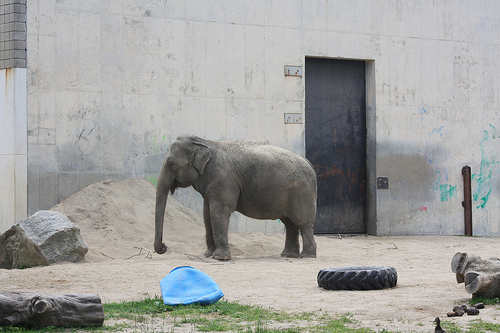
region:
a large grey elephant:
[141, 129, 329, 264]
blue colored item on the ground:
[156, 261, 226, 306]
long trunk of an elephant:
[150, 179, 173, 258]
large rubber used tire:
[312, 263, 402, 294]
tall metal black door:
[296, 50, 381, 237]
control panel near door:
[375, 173, 392, 193]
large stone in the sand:
[0, 205, 92, 270]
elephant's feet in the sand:
[199, 240, 321, 265]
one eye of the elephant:
[167, 157, 177, 170]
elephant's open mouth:
[165, 180, 180, 199]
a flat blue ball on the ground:
[144, 262, 255, 326]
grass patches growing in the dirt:
[233, 304, 262, 329]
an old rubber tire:
[323, 262, 414, 299]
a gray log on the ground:
[0, 282, 117, 331]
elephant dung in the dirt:
[446, 295, 494, 315]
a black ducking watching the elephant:
[434, 317, 447, 332]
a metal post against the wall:
[459, 162, 479, 237]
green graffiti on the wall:
[480, 142, 492, 230]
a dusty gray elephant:
[131, 137, 337, 256]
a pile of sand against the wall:
[89, 181, 148, 261]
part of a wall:
[404, 86, 451, 141]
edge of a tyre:
[341, 271, 371, 293]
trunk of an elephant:
[147, 210, 175, 239]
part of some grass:
[225, 302, 248, 319]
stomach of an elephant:
[235, 165, 287, 220]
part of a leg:
[208, 221, 220, 259]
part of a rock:
[33, 217, 68, 241]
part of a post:
[451, 192, 474, 243]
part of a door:
[326, 108, 360, 163]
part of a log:
[448, 260, 484, 297]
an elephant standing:
[151, 131, 321, 261]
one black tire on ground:
[314, 257, 401, 293]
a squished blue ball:
[157, 262, 227, 310]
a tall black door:
[293, 49, 385, 238]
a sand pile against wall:
[48, 177, 248, 261]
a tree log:
[0, 287, 107, 330]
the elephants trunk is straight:
[151, 176, 176, 258]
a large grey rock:
[0, 208, 92, 267]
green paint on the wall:
[434, 120, 495, 211]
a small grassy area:
[91, 293, 387, 330]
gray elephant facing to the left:
[120, 137, 382, 272]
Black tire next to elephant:
[330, 257, 402, 298]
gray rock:
[3, 195, 95, 281]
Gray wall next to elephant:
[0, 86, 168, 218]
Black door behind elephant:
[313, 51, 397, 213]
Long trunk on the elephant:
[138, 165, 178, 256]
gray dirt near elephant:
[93, 193, 146, 265]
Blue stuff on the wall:
[417, 118, 454, 224]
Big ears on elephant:
[183, 146, 218, 184]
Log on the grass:
[4, 285, 121, 324]